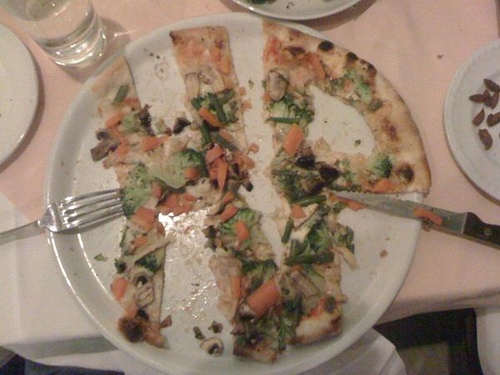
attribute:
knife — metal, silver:
[336, 187, 500, 249]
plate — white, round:
[41, 10, 437, 374]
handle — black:
[461, 209, 499, 250]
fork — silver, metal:
[0, 188, 128, 251]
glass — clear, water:
[3, 1, 113, 73]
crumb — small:
[201, 338, 227, 359]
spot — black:
[318, 38, 336, 53]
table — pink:
[338, 13, 499, 294]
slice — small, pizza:
[255, 22, 431, 205]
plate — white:
[443, 36, 499, 200]